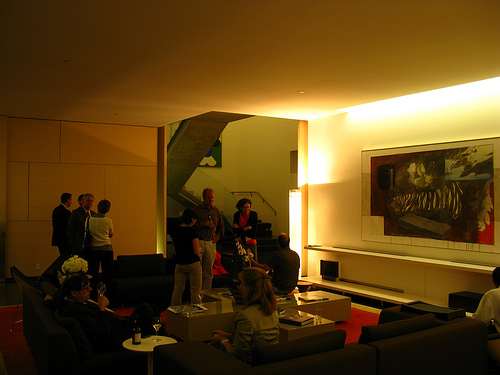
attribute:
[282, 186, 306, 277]
light — cylindrical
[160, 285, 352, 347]
table — short